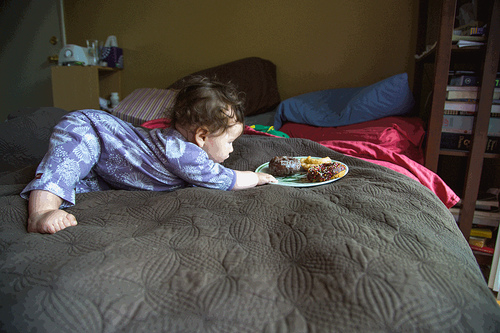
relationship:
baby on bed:
[37, 60, 264, 220] [119, 188, 444, 317]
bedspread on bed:
[6, 135, 499, 329] [0, 58, 500, 330]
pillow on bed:
[106, 80, 181, 129] [0, 58, 500, 330]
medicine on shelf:
[110, 90, 119, 104] [52, 60, 119, 112]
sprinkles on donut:
[320, 159, 346, 170] [269, 155, 304, 176]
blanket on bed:
[93, 193, 455, 325] [0, 58, 500, 330]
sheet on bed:
[138, 100, 467, 222] [0, 58, 500, 330]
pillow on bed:
[249, 72, 419, 137] [0, 58, 500, 330]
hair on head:
[183, 86, 241, 127] [172, 76, 246, 163]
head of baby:
[172, 76, 246, 163] [33, 75, 261, 233]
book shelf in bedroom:
[413, 0, 498, 255] [4, 6, 498, 330]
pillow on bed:
[176, 46, 316, 144] [0, 58, 500, 330]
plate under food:
[254, 152, 349, 188] [291, 130, 396, 185]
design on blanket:
[26, 132, 453, 331] [5, 108, 498, 331]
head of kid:
[159, 82, 262, 171] [26, 85, 272, 229]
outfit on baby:
[17, 107, 239, 209] [26, 74, 276, 235]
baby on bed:
[26, 74, 276, 235] [0, 107, 500, 329]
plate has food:
[250, 152, 346, 186] [262, 153, 343, 186]